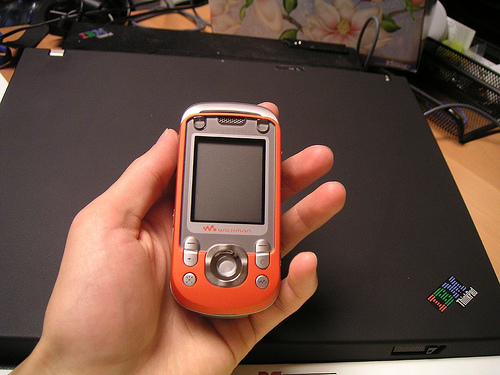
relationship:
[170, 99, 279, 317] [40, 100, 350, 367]
phone in hand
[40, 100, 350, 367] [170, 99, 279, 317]
hand holding phone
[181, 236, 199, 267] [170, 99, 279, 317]
button on phone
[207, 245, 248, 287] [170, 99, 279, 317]
button on phone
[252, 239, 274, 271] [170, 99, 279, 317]
button on phone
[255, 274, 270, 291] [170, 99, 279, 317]
button on phone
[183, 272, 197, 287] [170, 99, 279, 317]
button on phone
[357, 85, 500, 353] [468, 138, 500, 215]
laptop on table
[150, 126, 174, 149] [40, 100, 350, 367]
nails on hand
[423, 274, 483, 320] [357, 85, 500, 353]
logo on laptop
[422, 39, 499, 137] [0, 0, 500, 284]
holder on table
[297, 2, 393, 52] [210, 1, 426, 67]
flower on box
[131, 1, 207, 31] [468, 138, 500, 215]
wires on table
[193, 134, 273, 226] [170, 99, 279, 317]
screen on phone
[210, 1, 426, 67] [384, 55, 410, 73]
box of kleenex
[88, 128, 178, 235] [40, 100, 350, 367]
thumb on hand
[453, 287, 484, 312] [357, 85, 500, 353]
letters on laptop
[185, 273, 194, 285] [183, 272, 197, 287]
x on button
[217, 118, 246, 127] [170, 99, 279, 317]
speaker on phone